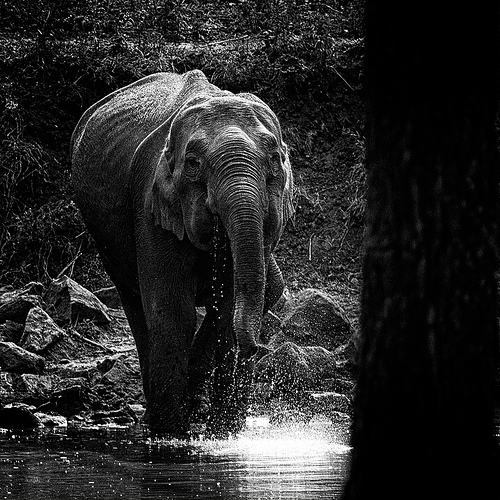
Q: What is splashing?
A: An elephant.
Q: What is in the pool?
A: Water.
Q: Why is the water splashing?
A: The elephant is splashing with its trunk.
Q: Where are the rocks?
A: Around the pond.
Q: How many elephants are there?
A: One.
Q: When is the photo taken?
A: Daytime.